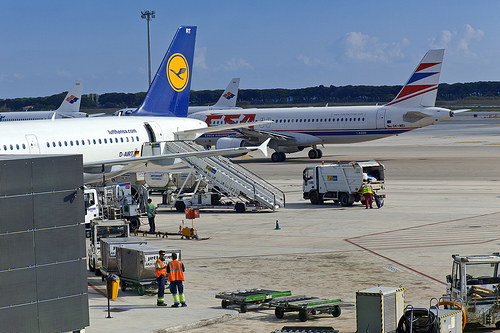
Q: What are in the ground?
A: Plane.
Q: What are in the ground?
A: Planes.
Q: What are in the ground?
A: Planes.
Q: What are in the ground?
A: Vehicles.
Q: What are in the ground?
A: Lines.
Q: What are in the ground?
A: Containers.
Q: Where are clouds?
A: In the sky.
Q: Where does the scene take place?
A: At the airport.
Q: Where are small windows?
A: On sides of planes.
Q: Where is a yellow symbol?
A: On plane's blue tail.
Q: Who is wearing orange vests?
A: Two men in foreground.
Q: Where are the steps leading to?
A: Left plane.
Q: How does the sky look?
A: Blue with some clouds.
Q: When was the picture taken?
A: During daytime.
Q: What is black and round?
A: Plane wheels.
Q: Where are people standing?
A: On the tarmac.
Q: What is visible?
A: An airplane?.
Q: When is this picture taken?
A: Day time.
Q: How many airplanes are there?
A: Four.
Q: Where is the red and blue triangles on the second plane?
A: The tail.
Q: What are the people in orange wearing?
A: Safety vests.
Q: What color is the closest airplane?
A: White blue and yellow.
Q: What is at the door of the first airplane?
A: Ladder.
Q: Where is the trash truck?
A: In front of the person in the yellow safety vest.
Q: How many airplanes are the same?
A: Two.